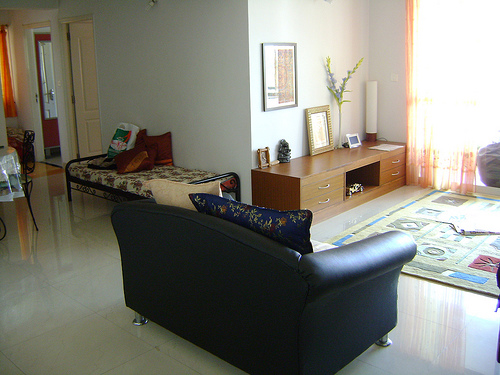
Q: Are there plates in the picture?
A: No, there are no plates.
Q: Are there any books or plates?
A: No, there are no plates or books.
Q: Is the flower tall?
A: Yes, the flower is tall.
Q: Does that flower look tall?
A: Yes, the flower is tall.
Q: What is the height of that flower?
A: The flower is tall.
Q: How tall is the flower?
A: The flower is tall.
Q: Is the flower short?
A: No, the flower is tall.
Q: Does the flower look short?
A: No, the flower is tall.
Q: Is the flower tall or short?
A: The flower is tall.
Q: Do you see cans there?
A: No, there are no cans.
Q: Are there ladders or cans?
A: No, there are no cans or ladders.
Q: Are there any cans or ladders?
A: No, there are no cans or ladders.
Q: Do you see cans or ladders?
A: No, there are no cans or ladders.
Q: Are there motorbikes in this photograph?
A: No, there are no motorbikes.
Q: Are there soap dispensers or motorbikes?
A: No, there are no motorbikes or soap dispensers.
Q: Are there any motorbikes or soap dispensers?
A: No, there are no motorbikes or soap dispensers.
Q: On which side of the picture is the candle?
A: The candle is on the right of the image.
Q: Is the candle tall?
A: Yes, the candle is tall.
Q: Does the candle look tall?
A: Yes, the candle is tall.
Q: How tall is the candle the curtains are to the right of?
A: The candle is tall.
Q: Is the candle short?
A: No, the candle is tall.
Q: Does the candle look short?
A: No, the candle is tall.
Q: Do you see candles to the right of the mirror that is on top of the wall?
A: Yes, there is a candle to the right of the mirror.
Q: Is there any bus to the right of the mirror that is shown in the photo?
A: No, there is a candle to the right of the mirror.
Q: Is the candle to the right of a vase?
A: No, the candle is to the right of the mirror.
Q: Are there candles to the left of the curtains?
A: Yes, there is a candle to the left of the curtains.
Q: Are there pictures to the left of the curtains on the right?
A: No, there is a candle to the left of the curtains.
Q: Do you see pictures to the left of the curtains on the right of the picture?
A: No, there is a candle to the left of the curtains.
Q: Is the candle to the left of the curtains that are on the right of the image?
A: Yes, the candle is to the left of the curtains.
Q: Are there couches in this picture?
A: Yes, there is a couch.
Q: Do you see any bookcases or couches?
A: Yes, there is a couch.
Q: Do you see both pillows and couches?
A: Yes, there are both a couch and pillows.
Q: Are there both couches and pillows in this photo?
A: Yes, there are both a couch and pillows.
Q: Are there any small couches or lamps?
A: Yes, there is a small couch.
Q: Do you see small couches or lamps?
A: Yes, there is a small couch.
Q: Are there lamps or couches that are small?
A: Yes, the couch is small.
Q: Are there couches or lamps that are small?
A: Yes, the couch is small.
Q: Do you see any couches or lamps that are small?
A: Yes, the couch is small.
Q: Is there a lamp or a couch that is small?
A: Yes, the couch is small.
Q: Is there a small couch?
A: Yes, there is a small couch.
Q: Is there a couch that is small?
A: Yes, there is a couch that is small.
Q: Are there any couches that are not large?
A: Yes, there is a small couch.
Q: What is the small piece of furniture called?
A: The piece of furniture is a couch.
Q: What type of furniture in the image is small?
A: The furniture is a couch.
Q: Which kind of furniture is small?
A: The furniture is a couch.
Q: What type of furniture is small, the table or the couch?
A: The couch is small.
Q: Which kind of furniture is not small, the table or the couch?
A: The table is not small.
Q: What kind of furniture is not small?
A: The furniture is a table.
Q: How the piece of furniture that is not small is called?
A: The piece of furniture is a table.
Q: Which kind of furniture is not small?
A: The furniture is a table.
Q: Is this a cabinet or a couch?
A: This is a couch.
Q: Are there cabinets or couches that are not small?
A: No, there is a couch but it is small.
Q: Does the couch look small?
A: Yes, the couch is small.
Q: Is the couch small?
A: Yes, the couch is small.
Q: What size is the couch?
A: The couch is small.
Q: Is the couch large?
A: No, the couch is small.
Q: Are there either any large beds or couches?
A: No, there is a couch but it is small.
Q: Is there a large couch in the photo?
A: No, there is a couch but it is small.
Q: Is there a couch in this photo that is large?
A: No, there is a couch but it is small.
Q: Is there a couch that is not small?
A: No, there is a couch but it is small.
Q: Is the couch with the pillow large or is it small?
A: The couch is small.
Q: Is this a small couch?
A: Yes, this is a small couch.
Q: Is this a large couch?
A: No, this is a small couch.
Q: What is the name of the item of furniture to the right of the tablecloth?
A: The piece of furniture is a couch.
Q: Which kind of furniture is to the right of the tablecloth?
A: The piece of furniture is a couch.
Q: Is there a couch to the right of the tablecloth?
A: Yes, there is a couch to the right of the tablecloth.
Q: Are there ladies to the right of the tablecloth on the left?
A: No, there is a couch to the right of the tablecloth.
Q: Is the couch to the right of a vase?
A: No, the couch is to the right of the tablecloth.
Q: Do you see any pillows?
A: Yes, there is a pillow.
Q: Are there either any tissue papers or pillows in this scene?
A: Yes, there is a pillow.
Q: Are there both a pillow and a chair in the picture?
A: Yes, there are both a pillow and a chair.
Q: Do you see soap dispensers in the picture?
A: No, there are no soap dispensers.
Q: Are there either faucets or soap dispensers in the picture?
A: No, there are no soap dispensers or faucets.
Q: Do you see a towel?
A: No, there are no towels.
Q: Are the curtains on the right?
A: Yes, the curtains are on the right of the image.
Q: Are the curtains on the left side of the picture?
A: No, the curtains are on the right of the image.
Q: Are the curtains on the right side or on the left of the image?
A: The curtains are on the right of the image.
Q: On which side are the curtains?
A: The curtains are on the right of the image.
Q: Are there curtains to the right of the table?
A: Yes, there are curtains to the right of the table.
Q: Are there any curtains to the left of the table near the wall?
A: No, the curtains are to the right of the table.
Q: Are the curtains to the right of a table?
A: Yes, the curtains are to the right of a table.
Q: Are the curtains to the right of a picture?
A: No, the curtains are to the right of a table.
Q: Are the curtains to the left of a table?
A: No, the curtains are to the right of a table.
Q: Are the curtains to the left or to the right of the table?
A: The curtains are to the right of the table.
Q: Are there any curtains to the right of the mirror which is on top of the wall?
A: Yes, there are curtains to the right of the mirror.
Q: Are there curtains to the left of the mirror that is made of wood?
A: No, the curtains are to the right of the mirror.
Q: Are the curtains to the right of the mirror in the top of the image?
A: Yes, the curtains are to the right of the mirror.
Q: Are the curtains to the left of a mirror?
A: No, the curtains are to the right of a mirror.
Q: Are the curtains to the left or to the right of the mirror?
A: The curtains are to the right of the mirror.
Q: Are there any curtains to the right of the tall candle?
A: Yes, there are curtains to the right of the candle.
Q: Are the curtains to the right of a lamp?
A: No, the curtains are to the right of the candle.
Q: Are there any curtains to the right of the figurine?
A: Yes, there are curtains to the right of the figurine.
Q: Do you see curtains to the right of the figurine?
A: Yes, there are curtains to the right of the figurine.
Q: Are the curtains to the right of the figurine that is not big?
A: Yes, the curtains are to the right of the figurine.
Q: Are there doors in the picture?
A: Yes, there is a door.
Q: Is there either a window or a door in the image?
A: Yes, there is a door.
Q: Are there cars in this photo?
A: No, there are no cars.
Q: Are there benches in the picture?
A: Yes, there is a bench.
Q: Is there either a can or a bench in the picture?
A: Yes, there is a bench.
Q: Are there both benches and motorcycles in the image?
A: No, there is a bench but no motorcycles.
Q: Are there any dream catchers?
A: No, there are no dream catchers.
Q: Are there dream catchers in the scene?
A: No, there are no dream catchers.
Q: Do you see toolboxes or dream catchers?
A: No, there are no dream catchers or toolboxes.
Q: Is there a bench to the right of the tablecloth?
A: Yes, there is a bench to the right of the tablecloth.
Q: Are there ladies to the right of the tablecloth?
A: No, there is a bench to the right of the tablecloth.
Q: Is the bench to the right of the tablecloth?
A: Yes, the bench is to the right of the tablecloth.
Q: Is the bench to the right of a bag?
A: No, the bench is to the right of the tablecloth.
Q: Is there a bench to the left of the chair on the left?
A: No, the bench is to the right of the chair.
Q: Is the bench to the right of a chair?
A: Yes, the bench is to the right of a chair.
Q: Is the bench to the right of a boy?
A: No, the bench is to the right of a chair.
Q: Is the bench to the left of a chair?
A: No, the bench is to the right of a chair.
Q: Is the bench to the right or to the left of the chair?
A: The bench is to the right of the chair.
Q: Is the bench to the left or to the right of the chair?
A: The bench is to the right of the chair.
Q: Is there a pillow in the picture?
A: Yes, there is a pillow.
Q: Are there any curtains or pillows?
A: Yes, there is a pillow.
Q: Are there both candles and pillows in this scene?
A: Yes, there are both a pillow and a candle.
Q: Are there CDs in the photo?
A: No, there are no cds.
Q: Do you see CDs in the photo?
A: No, there are no cds.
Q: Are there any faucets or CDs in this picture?
A: No, there are no CDs or faucets.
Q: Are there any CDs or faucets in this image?
A: No, there are no CDs or faucets.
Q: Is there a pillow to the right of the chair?
A: Yes, there is a pillow to the right of the chair.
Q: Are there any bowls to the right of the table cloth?
A: No, there is a pillow to the right of the table cloth.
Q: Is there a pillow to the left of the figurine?
A: Yes, there is a pillow to the left of the figurine.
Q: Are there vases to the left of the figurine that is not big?
A: No, there is a pillow to the left of the figurine.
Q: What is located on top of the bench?
A: The pillow is on top of the bench.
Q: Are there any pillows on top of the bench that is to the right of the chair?
A: Yes, there is a pillow on top of the bench.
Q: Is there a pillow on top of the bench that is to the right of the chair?
A: Yes, there is a pillow on top of the bench.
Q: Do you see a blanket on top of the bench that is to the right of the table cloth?
A: No, there is a pillow on top of the bench.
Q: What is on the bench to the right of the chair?
A: The pillow is on the bench.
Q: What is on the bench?
A: The pillow is on the bench.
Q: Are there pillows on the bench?
A: Yes, there is a pillow on the bench.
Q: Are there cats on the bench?
A: No, there is a pillow on the bench.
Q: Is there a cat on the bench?
A: No, there is a pillow on the bench.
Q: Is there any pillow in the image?
A: Yes, there is a pillow.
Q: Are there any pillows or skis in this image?
A: Yes, there is a pillow.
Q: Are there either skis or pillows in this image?
A: Yes, there is a pillow.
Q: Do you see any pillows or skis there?
A: Yes, there is a pillow.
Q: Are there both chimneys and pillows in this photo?
A: No, there is a pillow but no chimneys.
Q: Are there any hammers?
A: No, there are no hammers.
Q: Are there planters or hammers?
A: No, there are no hammers or planters.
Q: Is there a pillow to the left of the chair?
A: No, the pillow is to the right of the chair.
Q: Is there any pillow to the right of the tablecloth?
A: Yes, there is a pillow to the right of the tablecloth.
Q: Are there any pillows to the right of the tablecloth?
A: Yes, there is a pillow to the right of the tablecloth.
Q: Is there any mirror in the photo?
A: Yes, there is a mirror.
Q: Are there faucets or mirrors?
A: Yes, there is a mirror.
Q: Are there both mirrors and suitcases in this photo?
A: No, there is a mirror but no suitcases.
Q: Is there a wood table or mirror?
A: Yes, there is a wood mirror.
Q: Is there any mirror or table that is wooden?
A: Yes, the mirror is wooden.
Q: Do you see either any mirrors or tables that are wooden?
A: Yes, the mirror is wooden.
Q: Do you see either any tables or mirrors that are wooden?
A: Yes, the mirror is wooden.